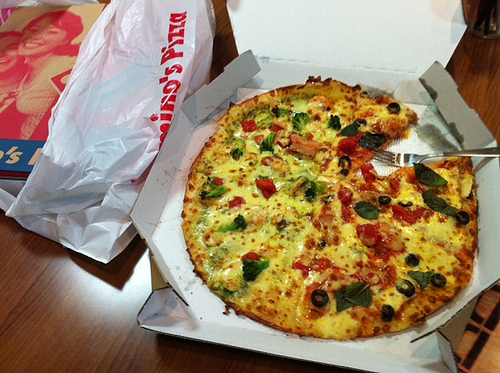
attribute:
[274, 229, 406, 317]
toppings — red 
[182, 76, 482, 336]
pie — pizza 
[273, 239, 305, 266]
cheese — gooey 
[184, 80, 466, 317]
pie — pizza 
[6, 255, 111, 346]
table — brown dinner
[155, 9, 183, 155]
letters — red 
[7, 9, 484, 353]
shop — pizza 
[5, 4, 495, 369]
table — wooden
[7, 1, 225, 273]
bag — plastic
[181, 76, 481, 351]
pizza — round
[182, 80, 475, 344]
cheese — yellow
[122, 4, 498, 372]
box — cardboard, pizza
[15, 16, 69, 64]
face — woman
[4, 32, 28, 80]
face — man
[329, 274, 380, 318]
leaves — green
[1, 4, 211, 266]
bag — white, pizza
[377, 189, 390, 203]
olives — black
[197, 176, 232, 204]
broccoli — green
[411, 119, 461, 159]
stain — grease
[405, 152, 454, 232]
spinach — green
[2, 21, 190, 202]
box — not open, pizza box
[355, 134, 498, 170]
fork — made of metal, silver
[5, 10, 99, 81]
woman — smiling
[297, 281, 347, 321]
olive — round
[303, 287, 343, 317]
olive — black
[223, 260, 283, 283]
broccoli — green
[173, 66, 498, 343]
pizza — personal pizza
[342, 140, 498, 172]
utensil — a metal eating utensil